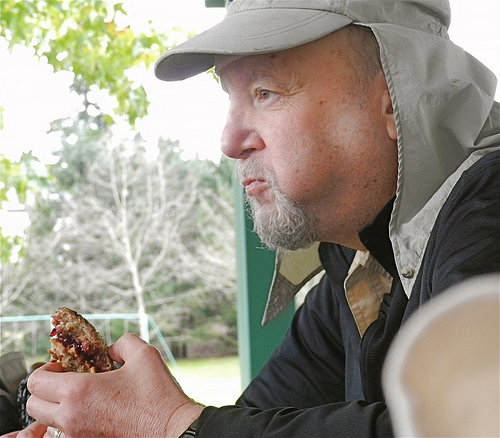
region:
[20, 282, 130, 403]
Sandwich in the man's hand.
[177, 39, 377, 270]
The man is eating.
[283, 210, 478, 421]
The jacket is black.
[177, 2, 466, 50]
Man is wearing a hat.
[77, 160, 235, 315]
Tree with no leaves in the background.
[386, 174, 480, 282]
The undershirt is grey.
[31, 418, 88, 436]
Man is wearing a ring.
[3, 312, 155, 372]
Fence in the background.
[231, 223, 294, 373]
The pillar is green.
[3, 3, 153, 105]
Leaves in the background.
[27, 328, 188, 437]
the hand of a man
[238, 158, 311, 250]
the grey beard of a man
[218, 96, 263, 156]
the nose of a man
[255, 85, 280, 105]
the eye of a man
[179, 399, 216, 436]
the watch of a man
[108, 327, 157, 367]
the thumb of a man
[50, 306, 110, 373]
a peanut butter and jelly sandwich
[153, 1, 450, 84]
a tan hat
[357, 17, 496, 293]
the tan flap of a hat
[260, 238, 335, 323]
the tan flap of a hat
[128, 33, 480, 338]
this is a man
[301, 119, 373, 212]
the man is light skinned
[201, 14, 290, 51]
this is a cap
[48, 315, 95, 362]
this is a snack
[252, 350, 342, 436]
this is a jacket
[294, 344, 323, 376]
the jacket is black in color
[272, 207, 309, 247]
these are the beads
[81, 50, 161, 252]
this is a tree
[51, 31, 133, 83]
these are the leaves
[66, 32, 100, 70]
the leaves are green in color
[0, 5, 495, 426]
old man eating a samich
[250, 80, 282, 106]
brown eye of old man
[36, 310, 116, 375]
peanut butter and jelly samich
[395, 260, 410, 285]
button on grey hat gear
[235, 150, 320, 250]
facial hair of an older man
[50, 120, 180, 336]
dead tree in background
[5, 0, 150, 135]
leaves of a healthy tree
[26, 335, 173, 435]
hand of an old man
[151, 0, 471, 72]
grey hat on mans head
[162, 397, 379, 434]
arm in a black hoodie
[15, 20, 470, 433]
man eating a sandwich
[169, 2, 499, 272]
man is wearing a hood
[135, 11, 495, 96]
the man is wearing a baseball cap over his hood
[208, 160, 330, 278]
the man has a beard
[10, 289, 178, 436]
hand holding the sandwich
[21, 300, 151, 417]
the sandwich is half-eaten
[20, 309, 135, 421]
The sandwich is peanut butter and jelly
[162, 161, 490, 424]
man wearing a grey jacket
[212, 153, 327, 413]
the window bar is green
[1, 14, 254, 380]
trees outside the window